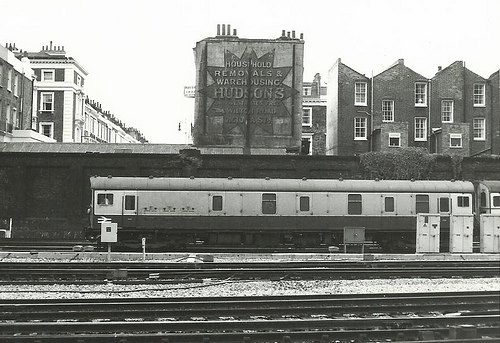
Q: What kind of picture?
A: Black and white.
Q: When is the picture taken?
A: Daytime.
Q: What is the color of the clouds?
A: White.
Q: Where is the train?
A: In the track.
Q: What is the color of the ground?
A: Grey.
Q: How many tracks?
A: 4.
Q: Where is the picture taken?
A: On the train tracks.